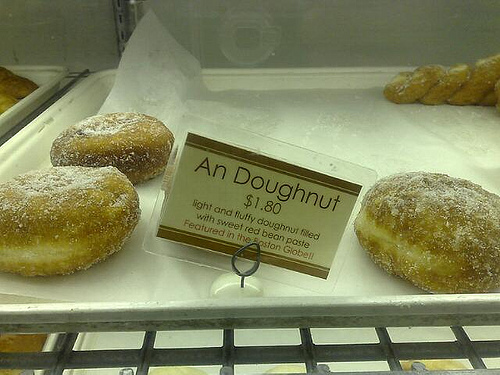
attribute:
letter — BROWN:
[194, 153, 211, 176]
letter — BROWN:
[210, 160, 231, 183]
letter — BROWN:
[231, 163, 251, 189]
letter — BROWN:
[250, 172, 266, 191]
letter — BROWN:
[264, 174, 276, 194]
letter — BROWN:
[275, 180, 293, 204]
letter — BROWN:
[290, 180, 305, 203]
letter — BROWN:
[303, 178, 320, 208]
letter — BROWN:
[318, 189, 331, 215]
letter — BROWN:
[330, 190, 343, 215]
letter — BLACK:
[192, 155, 213, 177]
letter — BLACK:
[208, 155, 233, 176]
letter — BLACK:
[231, 162, 251, 184]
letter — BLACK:
[250, 173, 267, 187]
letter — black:
[273, 178, 290, 213]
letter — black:
[292, 182, 307, 206]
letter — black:
[291, 180, 311, 209]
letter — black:
[319, 191, 333, 214]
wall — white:
[2, 4, 499, 77]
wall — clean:
[2, 2, 496, 70]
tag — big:
[150, 123, 366, 283]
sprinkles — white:
[1, 160, 132, 221]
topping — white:
[2, 155, 118, 222]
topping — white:
[60, 106, 140, 152]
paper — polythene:
[29, 6, 499, 303]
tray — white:
[2, 60, 498, 327]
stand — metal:
[2, 330, 498, 373]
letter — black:
[260, 178, 278, 198]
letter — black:
[329, 193, 339, 210]